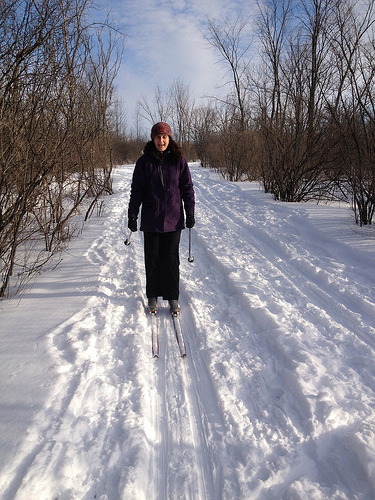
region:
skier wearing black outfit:
[131, 106, 200, 317]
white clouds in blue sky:
[117, 20, 133, 48]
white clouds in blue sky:
[133, 11, 157, 32]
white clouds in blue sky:
[177, 12, 200, 37]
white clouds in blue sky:
[229, 9, 245, 34]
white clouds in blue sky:
[208, 45, 247, 78]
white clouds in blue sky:
[106, 15, 142, 48]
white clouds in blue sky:
[137, 42, 162, 50]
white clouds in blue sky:
[157, 47, 190, 71]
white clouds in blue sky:
[131, 69, 169, 91]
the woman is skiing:
[110, 106, 232, 356]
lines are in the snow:
[107, 309, 233, 483]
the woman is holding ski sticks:
[87, 186, 210, 300]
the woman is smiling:
[131, 115, 182, 163]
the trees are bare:
[235, 7, 348, 219]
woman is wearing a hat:
[133, 110, 182, 150]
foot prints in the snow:
[214, 229, 314, 385]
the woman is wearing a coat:
[105, 122, 206, 261]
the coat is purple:
[108, 138, 220, 239]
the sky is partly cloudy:
[109, 0, 249, 134]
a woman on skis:
[76, 88, 217, 396]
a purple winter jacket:
[105, 133, 211, 238]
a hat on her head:
[139, 107, 179, 150]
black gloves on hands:
[180, 213, 205, 249]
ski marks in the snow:
[120, 315, 298, 497]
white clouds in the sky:
[110, 8, 284, 137]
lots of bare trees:
[6, 38, 371, 300]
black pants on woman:
[121, 217, 206, 340]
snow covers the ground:
[4, 150, 373, 461]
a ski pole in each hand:
[108, 199, 234, 305]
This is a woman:
[96, 118, 244, 361]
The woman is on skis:
[119, 116, 207, 361]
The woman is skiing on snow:
[107, 108, 225, 366]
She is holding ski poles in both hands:
[113, 190, 218, 273]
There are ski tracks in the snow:
[135, 377, 220, 494]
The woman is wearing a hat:
[138, 116, 181, 137]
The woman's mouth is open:
[152, 138, 169, 150]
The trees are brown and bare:
[220, 5, 368, 201]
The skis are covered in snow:
[144, 310, 191, 358]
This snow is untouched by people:
[8, 311, 40, 383]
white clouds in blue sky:
[147, 23, 186, 56]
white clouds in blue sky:
[122, 61, 157, 94]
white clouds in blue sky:
[192, 50, 212, 82]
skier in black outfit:
[122, 110, 204, 342]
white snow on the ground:
[117, 387, 174, 433]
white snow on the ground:
[274, 379, 321, 421]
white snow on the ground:
[265, 256, 308, 313]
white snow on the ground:
[41, 358, 70, 389]